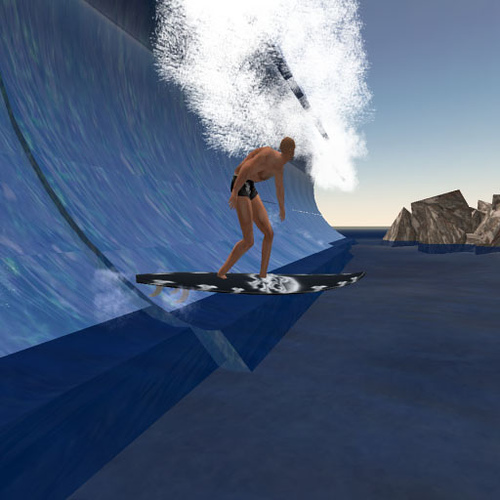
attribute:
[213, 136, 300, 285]
man — computer generated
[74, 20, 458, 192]
virtual wave — water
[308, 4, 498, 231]
sky — clear, blue, virtual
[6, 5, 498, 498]
photo — 3D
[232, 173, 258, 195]
shorts — black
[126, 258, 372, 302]
surfboard — black, white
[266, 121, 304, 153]
hair — blone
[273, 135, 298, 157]
head — man's